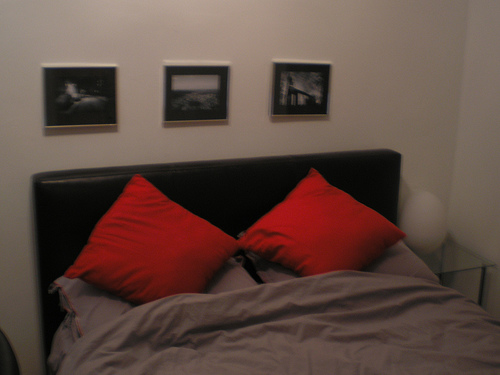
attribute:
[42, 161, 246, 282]
pillow — red, tan, bed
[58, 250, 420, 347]
sheet — tan, brown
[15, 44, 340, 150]
picture — frame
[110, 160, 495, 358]
bed — black, queen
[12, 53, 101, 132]
photo — gray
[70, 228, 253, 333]
comforter — gray, white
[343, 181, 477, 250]
light — white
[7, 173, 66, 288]
post — black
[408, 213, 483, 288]
nightstand — glass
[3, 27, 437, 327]
frame — black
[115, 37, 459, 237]
bathroom — red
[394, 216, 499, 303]
table — glass